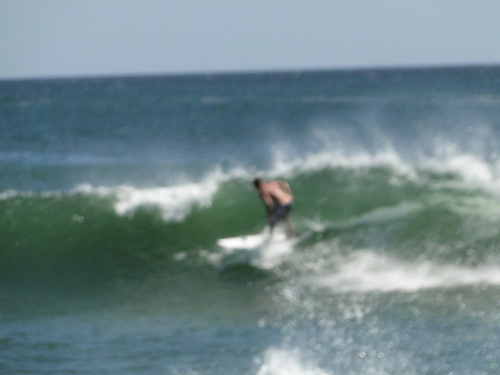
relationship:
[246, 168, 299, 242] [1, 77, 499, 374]
surfer in water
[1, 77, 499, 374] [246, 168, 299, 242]
water surrounding surfer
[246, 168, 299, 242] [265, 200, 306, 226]
surfer wearing shorts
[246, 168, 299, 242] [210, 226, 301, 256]
surfer on board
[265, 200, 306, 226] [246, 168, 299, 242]
shorts on surfer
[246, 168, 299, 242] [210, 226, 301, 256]
surfer on a board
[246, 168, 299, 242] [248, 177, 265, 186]
surfer has hair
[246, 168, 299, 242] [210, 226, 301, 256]
surfer riding board